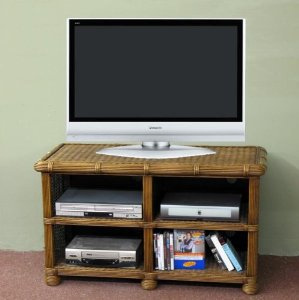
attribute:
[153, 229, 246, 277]
books — collection 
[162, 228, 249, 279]
dvds — boxed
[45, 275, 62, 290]
stand — brown, round, support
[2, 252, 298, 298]
floor — carpeted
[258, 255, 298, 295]
carpet — red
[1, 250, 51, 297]
carpet — red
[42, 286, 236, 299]
carpet — red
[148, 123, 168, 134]
logo — company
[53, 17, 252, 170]
tv — silver, flat screen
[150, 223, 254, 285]
dvds — cassettes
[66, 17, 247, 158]
television — off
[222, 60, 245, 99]
ground — silver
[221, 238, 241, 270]
tape — three , vhs 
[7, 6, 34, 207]
wall — light green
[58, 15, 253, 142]
tv — flat screen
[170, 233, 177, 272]
dvd — tapes, collection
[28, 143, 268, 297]
television stand — small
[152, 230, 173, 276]
books — neatly stacked together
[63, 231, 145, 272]
vcr player — black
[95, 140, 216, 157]
stand — white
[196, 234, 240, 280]
video — cassettes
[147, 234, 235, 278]
collection — books 